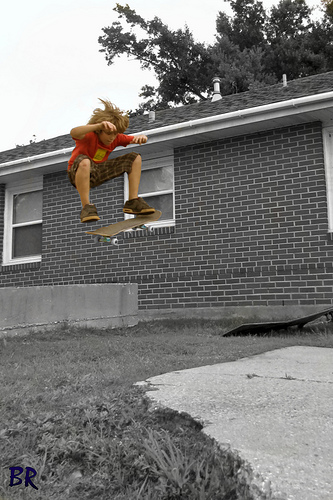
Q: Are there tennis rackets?
A: No, there are no tennis rackets.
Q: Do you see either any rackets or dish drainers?
A: No, there are no rackets or dish drainers.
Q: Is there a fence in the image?
A: No, there are no fences.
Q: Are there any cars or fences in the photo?
A: No, there are no fences or cars.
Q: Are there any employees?
A: No, there are no employees.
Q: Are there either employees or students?
A: No, there are no employees or students.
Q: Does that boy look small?
A: Yes, the boy is small.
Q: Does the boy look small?
A: Yes, the boy is small.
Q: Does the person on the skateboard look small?
A: Yes, the boy is small.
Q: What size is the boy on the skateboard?
A: The boy is small.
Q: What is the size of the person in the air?
A: The boy is small.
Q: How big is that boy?
A: The boy is small.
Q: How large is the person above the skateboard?
A: The boy is small.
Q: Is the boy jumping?
A: Yes, the boy is jumping.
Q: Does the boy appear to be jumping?
A: Yes, the boy is jumping.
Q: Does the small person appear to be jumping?
A: Yes, the boy is jumping.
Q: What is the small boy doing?
A: The boy is jumping.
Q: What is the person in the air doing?
A: The boy is jumping.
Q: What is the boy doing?
A: The boy is jumping.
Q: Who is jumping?
A: The boy is jumping.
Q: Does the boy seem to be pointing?
A: No, the boy is jumping.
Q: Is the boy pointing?
A: No, the boy is jumping.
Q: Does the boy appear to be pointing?
A: No, the boy is jumping.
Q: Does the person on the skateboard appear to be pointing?
A: No, the boy is jumping.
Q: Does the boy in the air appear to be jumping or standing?
A: The boy is jumping.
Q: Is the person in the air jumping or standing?
A: The boy is jumping.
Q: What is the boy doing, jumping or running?
A: The boy is jumping.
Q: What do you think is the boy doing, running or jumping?
A: The boy is jumping.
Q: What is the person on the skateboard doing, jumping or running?
A: The boy is jumping.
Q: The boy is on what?
A: The boy is on the skateboard.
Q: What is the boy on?
A: The boy is on the skateboard.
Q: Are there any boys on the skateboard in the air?
A: Yes, there is a boy on the skateboard.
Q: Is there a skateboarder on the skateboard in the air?
A: No, there is a boy on the skateboard.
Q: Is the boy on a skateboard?
A: Yes, the boy is on a skateboard.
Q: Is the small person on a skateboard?
A: Yes, the boy is on a skateboard.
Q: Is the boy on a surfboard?
A: No, the boy is on a skateboard.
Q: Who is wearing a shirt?
A: The boy is wearing a shirt.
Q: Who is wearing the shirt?
A: The boy is wearing a shirt.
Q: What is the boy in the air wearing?
A: The boy is wearing a shirt.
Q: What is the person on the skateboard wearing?
A: The boy is wearing a shirt.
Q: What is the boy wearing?
A: The boy is wearing a shirt.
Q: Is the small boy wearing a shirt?
A: Yes, the boy is wearing a shirt.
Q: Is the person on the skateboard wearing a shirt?
A: Yes, the boy is wearing a shirt.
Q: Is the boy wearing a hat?
A: No, the boy is wearing a shirt.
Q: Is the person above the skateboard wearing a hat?
A: No, the boy is wearing a shirt.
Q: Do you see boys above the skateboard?
A: Yes, there is a boy above the skateboard.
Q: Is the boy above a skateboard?
A: Yes, the boy is above a skateboard.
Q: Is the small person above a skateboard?
A: Yes, the boy is above a skateboard.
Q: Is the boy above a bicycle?
A: No, the boy is above a skateboard.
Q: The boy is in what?
A: The boy is in the air.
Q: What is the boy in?
A: The boy is in the air.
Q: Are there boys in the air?
A: Yes, there is a boy in the air.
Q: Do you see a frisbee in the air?
A: No, there is a boy in the air.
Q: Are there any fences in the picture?
A: No, there are no fences.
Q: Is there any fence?
A: No, there are no fences.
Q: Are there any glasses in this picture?
A: No, there are no glasses.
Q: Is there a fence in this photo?
A: No, there are no fences.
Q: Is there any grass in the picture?
A: Yes, there is grass.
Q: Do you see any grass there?
A: Yes, there is grass.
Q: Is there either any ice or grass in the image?
A: Yes, there is grass.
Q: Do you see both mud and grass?
A: No, there is grass but no mud.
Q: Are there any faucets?
A: No, there are no faucets.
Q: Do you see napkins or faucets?
A: No, there are no faucets or napkins.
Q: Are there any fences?
A: No, there are no fences.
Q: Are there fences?
A: No, there are no fences.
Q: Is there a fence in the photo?
A: No, there are no fences.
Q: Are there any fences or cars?
A: No, there are no fences or cars.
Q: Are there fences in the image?
A: No, there are no fences.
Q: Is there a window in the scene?
A: Yes, there is a window.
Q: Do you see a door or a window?
A: Yes, there is a window.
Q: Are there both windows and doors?
A: No, there is a window but no doors.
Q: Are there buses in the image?
A: No, there are no buses.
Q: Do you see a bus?
A: No, there are no buses.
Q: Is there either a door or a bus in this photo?
A: No, there are no buses or doors.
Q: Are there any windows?
A: Yes, there is a window.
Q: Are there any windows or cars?
A: Yes, there is a window.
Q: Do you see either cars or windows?
A: Yes, there is a window.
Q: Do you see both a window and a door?
A: No, there is a window but no doors.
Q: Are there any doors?
A: No, there are no doors.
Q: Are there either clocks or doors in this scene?
A: No, there are no doors or clocks.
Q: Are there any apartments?
A: No, there are no apartments.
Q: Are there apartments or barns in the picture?
A: No, there are no apartments or barns.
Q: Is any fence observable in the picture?
A: No, there are no fences.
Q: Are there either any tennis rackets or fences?
A: No, there are no fences or tennis rackets.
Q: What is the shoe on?
A: The shoe is on the skateboard.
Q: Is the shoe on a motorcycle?
A: No, the shoe is on the skateboard.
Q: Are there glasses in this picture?
A: No, there are no glasses.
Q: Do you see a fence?
A: No, there are no fences.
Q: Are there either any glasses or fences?
A: No, there are no fences or glasses.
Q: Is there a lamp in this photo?
A: No, there are no lamps.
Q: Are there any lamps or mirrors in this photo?
A: No, there are no lamps or mirrors.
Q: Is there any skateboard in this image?
A: Yes, there is a skateboard.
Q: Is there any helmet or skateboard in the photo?
A: Yes, there is a skateboard.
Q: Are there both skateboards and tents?
A: No, there is a skateboard but no tents.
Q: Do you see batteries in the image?
A: No, there are no batteries.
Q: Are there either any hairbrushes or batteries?
A: No, there are no batteries or hairbrushes.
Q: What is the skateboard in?
A: The skateboard is in the air.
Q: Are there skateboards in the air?
A: Yes, there is a skateboard in the air.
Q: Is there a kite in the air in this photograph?
A: No, there is a skateboard in the air.